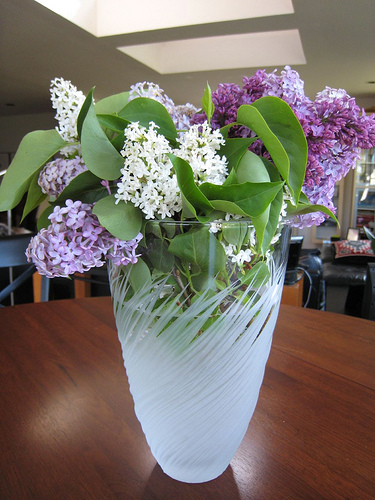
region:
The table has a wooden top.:
[1, 295, 373, 498]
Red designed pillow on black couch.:
[333, 239, 373, 257]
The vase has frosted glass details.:
[102, 221, 291, 485]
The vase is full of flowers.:
[0, 66, 373, 483]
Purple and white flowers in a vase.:
[2, 66, 373, 480]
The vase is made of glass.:
[106, 220, 289, 482]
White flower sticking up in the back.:
[50, 76, 94, 141]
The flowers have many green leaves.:
[1, 66, 374, 280]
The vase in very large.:
[108, 219, 292, 482]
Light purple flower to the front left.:
[25, 199, 142, 277]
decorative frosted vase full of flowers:
[104, 214, 280, 481]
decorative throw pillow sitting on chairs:
[333, 240, 373, 261]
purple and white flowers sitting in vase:
[9, 67, 373, 346]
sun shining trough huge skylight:
[34, 0, 308, 36]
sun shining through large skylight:
[119, 26, 308, 82]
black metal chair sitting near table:
[0, 237, 111, 302]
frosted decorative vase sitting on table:
[105, 213, 257, 484]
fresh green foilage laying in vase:
[15, 82, 312, 280]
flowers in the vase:
[12, 62, 357, 396]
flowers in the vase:
[9, 72, 319, 496]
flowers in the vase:
[22, 70, 293, 495]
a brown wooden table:
[259, 327, 358, 496]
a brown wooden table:
[11, 309, 132, 479]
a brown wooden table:
[25, 344, 145, 458]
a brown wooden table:
[9, 323, 146, 489]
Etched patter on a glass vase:
[197, 283, 245, 304]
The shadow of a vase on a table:
[142, 485, 221, 499]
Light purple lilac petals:
[49, 250, 69, 265]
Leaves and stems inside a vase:
[172, 276, 201, 299]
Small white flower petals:
[147, 189, 164, 204]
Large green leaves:
[271, 125, 305, 200]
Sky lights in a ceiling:
[88, 6, 209, 12]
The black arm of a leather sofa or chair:
[306, 262, 324, 297]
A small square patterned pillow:
[335, 239, 370, 251]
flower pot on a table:
[6, 69, 358, 484]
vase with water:
[92, 214, 289, 487]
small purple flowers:
[13, 202, 148, 277]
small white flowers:
[95, 114, 240, 239]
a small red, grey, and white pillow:
[325, 234, 371, 261]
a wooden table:
[0, 280, 371, 494]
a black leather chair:
[308, 229, 373, 312]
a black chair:
[1, 230, 117, 301]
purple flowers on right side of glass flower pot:
[192, 66, 372, 231]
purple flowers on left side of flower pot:
[23, 151, 140, 279]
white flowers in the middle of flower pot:
[48, 74, 229, 226]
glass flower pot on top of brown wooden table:
[104, 211, 287, 485]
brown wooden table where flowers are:
[1, 294, 372, 497]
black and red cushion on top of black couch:
[329, 235, 373, 259]